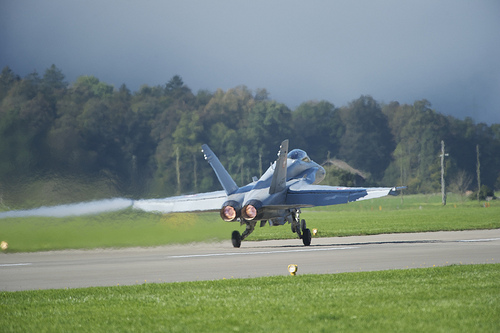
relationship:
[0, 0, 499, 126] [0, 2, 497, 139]
clouds in sky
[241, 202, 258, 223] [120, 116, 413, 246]
turbine of fighter jet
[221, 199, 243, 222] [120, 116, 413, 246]
engines of fighter jet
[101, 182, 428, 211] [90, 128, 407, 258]
wings of fighter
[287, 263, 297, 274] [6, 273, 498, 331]
light to side of grass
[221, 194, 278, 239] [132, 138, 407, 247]
engines on back of airplane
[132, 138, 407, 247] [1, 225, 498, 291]
airplane on runway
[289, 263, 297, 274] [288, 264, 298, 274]
light with cover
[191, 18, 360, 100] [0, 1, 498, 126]
clouds in sky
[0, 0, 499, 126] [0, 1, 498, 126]
clouds in sky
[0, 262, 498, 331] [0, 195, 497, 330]
grass in field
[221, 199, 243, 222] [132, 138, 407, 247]
engines on airplane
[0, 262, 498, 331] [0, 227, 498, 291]
grass beside airport runway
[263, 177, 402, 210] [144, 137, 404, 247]
right wing on plane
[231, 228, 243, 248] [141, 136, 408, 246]
tire on airplane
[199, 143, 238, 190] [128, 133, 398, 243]
fin on plane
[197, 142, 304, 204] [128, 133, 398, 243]
tail on plane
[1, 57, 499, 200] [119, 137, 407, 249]
tree line behind plane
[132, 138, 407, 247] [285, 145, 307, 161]
airplane on cockpit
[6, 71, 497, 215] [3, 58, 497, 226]
forest in background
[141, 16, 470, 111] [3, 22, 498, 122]
sky in background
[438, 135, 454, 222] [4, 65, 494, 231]
wooden poles in distance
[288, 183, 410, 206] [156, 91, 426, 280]
wings of plane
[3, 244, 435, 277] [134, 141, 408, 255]
runway beneath plane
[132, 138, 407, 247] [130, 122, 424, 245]
airplane nosing up for takeoff